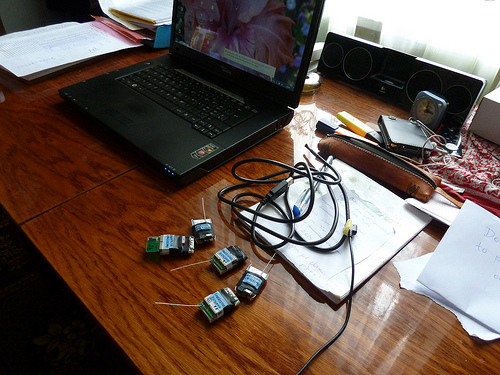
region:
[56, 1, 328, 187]
A black laptop, powered on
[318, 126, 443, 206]
A leather pencil or glasses case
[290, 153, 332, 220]
A blue ink pen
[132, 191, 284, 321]
Five electrical or technological gizmos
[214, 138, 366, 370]
A black cable with a USB end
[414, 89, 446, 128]
A small blue clock showing three o'clock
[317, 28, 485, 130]
A black bar with four circles, possibly a speaker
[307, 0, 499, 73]
Opaque window sheers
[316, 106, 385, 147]
Yellow and orange highlighters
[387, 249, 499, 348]
A piece of paper with a torn edge under a handwritten note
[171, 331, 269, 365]
shiny brown wood surface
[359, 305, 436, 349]
shadow on the desk surface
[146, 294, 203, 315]
tiny white straw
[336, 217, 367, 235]
blue and white edge of power cord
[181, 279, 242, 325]
small blue and green box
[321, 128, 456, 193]
small brown leather pouch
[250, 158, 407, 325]
stack of white paper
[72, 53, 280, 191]
base of black lap top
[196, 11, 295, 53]
large delicate pink flower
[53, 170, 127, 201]
crack on top of desk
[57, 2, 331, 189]
The laptop is black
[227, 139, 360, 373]
The wire is on the desk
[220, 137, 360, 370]
The wire is black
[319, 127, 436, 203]
Long narrow brown case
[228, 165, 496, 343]
White papers on the desk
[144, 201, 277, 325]
Green and black chips with blue labels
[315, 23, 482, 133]
The speaker is black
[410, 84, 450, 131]
The clock is blue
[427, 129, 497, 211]
Red and white cloth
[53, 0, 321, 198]
The computer screen is on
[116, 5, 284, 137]
this is a laptop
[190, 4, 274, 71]
the laptop is on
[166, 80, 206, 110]
these are the keyboards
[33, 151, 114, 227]
this is the table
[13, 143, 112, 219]
the table is wooden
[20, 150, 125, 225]
the table is brown in color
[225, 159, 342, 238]
these are the cables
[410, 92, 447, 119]
this is an alarm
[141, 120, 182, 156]
the laptop is black in color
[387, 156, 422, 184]
this is a bag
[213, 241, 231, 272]
Red and white rope on top of table.Red and white rope on top of table.